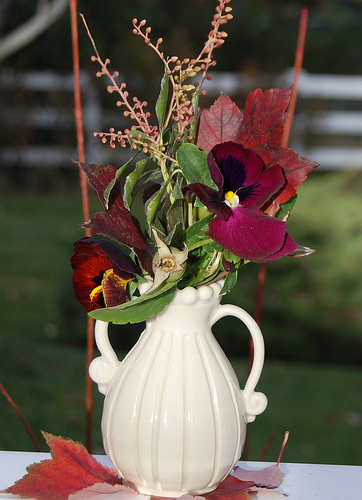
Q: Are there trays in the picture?
A: No, there are no trays.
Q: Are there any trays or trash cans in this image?
A: No, there are no trays or trash cans.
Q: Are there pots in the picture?
A: No, there are no pots.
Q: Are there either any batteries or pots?
A: No, there are no pots or batteries.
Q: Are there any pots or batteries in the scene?
A: No, there are no pots or batteries.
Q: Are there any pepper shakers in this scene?
A: No, there are no pepper shakers.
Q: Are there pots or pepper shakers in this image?
A: No, there are no pepper shakers or pots.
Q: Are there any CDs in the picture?
A: No, there are no cds.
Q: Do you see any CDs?
A: No, there are no cds.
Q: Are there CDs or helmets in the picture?
A: No, there are no CDs or helmets.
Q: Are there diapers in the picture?
A: No, there are no diapers.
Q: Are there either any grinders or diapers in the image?
A: No, there are no diapers or grinders.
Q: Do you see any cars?
A: No, there are no cars.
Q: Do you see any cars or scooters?
A: No, there are no cars or scooters.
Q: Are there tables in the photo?
A: Yes, there is a table.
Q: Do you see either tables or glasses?
A: Yes, there is a table.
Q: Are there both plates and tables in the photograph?
A: No, there is a table but no plates.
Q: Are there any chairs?
A: No, there are no chairs.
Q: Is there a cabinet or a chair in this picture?
A: No, there are no chairs or cabinets.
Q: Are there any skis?
A: No, there are no skis.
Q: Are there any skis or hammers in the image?
A: No, there are no skis or hammers.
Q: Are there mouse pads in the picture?
A: No, there are no mouse pads.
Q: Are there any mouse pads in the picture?
A: No, there are no mouse pads.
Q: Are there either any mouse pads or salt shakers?
A: No, there are no mouse pads or salt shakers.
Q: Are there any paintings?
A: No, there are no paintings.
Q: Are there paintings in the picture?
A: No, there are no paintings.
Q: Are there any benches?
A: No, there are no benches.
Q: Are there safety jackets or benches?
A: No, there are no benches or safety jackets.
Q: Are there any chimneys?
A: No, there are no chimneys.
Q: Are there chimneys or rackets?
A: No, there are no chimneys or rackets.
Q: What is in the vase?
A: The flowers are in the vase.